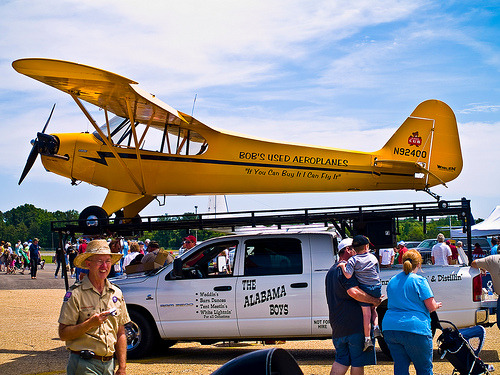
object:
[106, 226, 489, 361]
pick up truck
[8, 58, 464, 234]
airplane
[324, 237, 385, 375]
man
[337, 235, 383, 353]
child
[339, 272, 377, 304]
arms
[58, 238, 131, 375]
man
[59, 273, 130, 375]
uniform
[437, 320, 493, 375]
stroller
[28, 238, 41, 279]
person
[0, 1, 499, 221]
sky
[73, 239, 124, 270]
cowboy hat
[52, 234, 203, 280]
crowd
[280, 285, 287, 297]
writing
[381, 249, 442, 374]
woman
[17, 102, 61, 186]
propeller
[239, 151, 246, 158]
writing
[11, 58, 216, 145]
wing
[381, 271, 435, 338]
shirt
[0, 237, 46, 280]
group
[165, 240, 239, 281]
window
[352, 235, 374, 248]
hat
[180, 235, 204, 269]
man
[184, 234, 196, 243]
hat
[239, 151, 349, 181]
advertisement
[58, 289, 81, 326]
sleeve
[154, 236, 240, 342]
door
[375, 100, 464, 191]
tail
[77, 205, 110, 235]
wheels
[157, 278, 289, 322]
advertisement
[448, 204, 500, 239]
tent